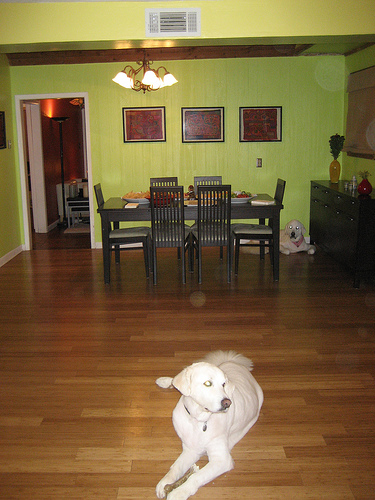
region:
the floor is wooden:
[108, 464, 141, 494]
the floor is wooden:
[275, 465, 290, 484]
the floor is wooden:
[273, 460, 290, 495]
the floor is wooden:
[254, 450, 270, 471]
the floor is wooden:
[246, 475, 256, 492]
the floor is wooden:
[266, 471, 279, 487]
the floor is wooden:
[251, 472, 264, 494]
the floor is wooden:
[251, 475, 257, 487]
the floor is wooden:
[287, 480, 292, 488]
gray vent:
[144, 10, 201, 40]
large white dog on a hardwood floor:
[152, 348, 266, 499]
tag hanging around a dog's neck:
[181, 400, 215, 431]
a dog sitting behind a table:
[240, 215, 317, 260]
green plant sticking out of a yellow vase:
[325, 131, 346, 182]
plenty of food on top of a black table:
[98, 185, 279, 276]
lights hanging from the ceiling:
[104, 49, 183, 94]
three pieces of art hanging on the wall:
[120, 104, 285, 144]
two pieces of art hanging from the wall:
[178, 106, 284, 143]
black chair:
[147, 182, 192, 289]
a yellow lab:
[110, 354, 303, 485]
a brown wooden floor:
[29, 311, 159, 391]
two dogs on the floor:
[107, 196, 350, 454]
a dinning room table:
[70, 171, 295, 275]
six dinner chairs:
[75, 169, 308, 276]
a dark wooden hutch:
[293, 159, 374, 275]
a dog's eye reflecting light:
[197, 373, 218, 393]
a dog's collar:
[180, 400, 218, 434]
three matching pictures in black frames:
[102, 101, 286, 150]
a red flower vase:
[353, 164, 374, 200]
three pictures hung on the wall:
[116, 97, 288, 149]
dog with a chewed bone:
[136, 331, 283, 498]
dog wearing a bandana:
[229, 212, 332, 267]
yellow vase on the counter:
[308, 116, 349, 189]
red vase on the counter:
[350, 165, 371, 197]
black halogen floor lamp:
[43, 106, 78, 235]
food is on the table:
[107, 174, 278, 220]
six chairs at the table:
[70, 145, 308, 289]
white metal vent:
[136, 7, 204, 42]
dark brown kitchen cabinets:
[307, 184, 368, 267]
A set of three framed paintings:
[113, 103, 299, 151]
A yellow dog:
[130, 347, 284, 498]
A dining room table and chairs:
[85, 173, 291, 302]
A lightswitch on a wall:
[252, 152, 269, 171]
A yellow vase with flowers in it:
[321, 129, 348, 185]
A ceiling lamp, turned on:
[100, 46, 189, 98]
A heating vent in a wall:
[138, 7, 206, 39]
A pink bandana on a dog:
[291, 233, 309, 249]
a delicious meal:
[116, 192, 262, 205]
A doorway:
[11, 90, 98, 254]